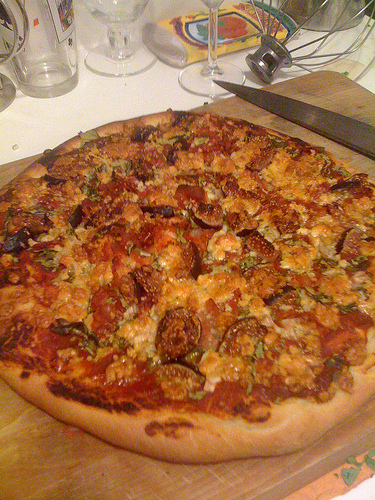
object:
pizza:
[0, 107, 375, 468]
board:
[0, 68, 374, 499]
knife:
[211, 77, 375, 162]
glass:
[177, 0, 247, 100]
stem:
[207, 9, 218, 67]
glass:
[83, 0, 159, 80]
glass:
[0, 0, 80, 100]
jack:
[46, 0, 77, 46]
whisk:
[243, 0, 373, 86]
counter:
[0, 0, 375, 500]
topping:
[152, 305, 203, 365]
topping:
[245, 146, 277, 173]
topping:
[247, 229, 276, 258]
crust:
[115, 395, 303, 468]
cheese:
[165, 273, 231, 303]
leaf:
[340, 465, 362, 489]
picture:
[195, 14, 249, 43]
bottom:
[178, 58, 247, 98]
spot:
[144, 416, 195, 440]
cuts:
[202, 464, 245, 499]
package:
[140, 0, 300, 70]